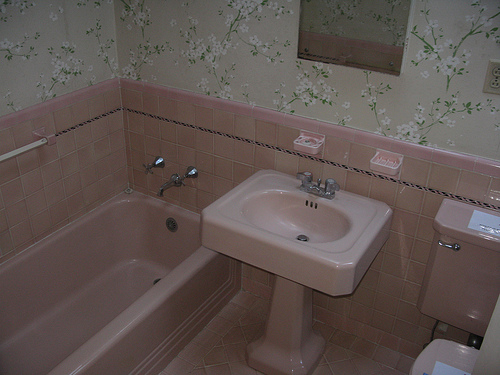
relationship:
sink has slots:
[202, 168, 391, 373] [304, 197, 318, 210]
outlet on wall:
[438, 320, 451, 337] [119, 2, 498, 369]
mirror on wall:
[296, 3, 415, 78] [119, 2, 498, 369]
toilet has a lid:
[408, 193, 499, 375] [411, 338, 484, 374]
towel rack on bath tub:
[1, 137, 63, 165] [1, 185, 247, 374]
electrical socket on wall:
[484, 57, 499, 103] [119, 2, 498, 369]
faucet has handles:
[296, 170, 337, 197] [300, 170, 337, 189]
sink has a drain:
[202, 168, 391, 373] [296, 231, 308, 241]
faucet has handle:
[296, 170, 337, 197] [435, 237, 463, 254]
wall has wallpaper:
[119, 2, 498, 369] [3, 2, 498, 177]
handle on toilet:
[435, 237, 463, 254] [408, 193, 499, 375]